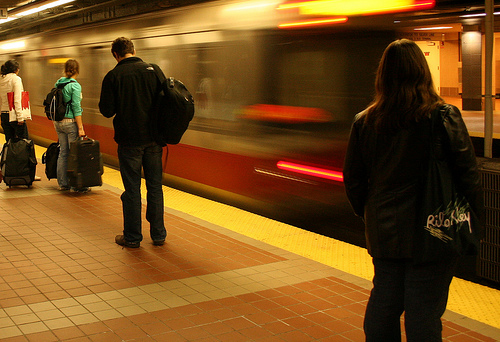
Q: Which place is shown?
A: It is a sidewalk.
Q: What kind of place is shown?
A: It is a sidewalk.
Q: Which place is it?
A: It is a sidewalk.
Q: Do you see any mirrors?
A: No, there are no mirrors.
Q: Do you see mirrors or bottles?
A: No, there are no mirrors or bottles.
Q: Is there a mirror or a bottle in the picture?
A: No, there are no mirrors or bottles.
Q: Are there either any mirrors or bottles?
A: No, there are no mirrors or bottles.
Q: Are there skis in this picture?
A: No, there are no skis.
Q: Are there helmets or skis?
A: No, there are no skis or helmets.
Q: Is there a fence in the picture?
A: No, there are no fences.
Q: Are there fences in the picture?
A: No, there are no fences.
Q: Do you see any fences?
A: No, there are no fences.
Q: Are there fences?
A: No, there are no fences.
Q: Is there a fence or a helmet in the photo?
A: No, there are no fences or helmets.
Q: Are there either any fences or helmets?
A: No, there are no fences or helmets.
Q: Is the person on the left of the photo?
A: Yes, the person is on the left of the image.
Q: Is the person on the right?
A: No, the person is on the left of the image.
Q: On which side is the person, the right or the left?
A: The person is on the left of the image.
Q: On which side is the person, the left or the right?
A: The person is on the left of the image.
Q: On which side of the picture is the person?
A: The person is on the left of the image.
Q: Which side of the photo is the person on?
A: The person is on the left of the image.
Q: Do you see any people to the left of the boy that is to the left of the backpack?
A: Yes, there is a person to the left of the boy.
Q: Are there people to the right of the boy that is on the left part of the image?
A: No, the person is to the left of the boy.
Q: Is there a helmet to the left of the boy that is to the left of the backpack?
A: No, there is a person to the left of the boy.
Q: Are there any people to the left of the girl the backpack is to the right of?
A: Yes, there is a person to the left of the girl.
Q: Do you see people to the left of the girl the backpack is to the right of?
A: Yes, there is a person to the left of the girl.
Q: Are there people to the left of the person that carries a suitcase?
A: Yes, there is a person to the left of the girl.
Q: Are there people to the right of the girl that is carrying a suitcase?
A: No, the person is to the left of the girl.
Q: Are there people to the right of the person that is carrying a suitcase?
A: No, the person is to the left of the girl.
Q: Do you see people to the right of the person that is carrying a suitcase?
A: No, the person is to the left of the girl.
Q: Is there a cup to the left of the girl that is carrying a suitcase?
A: No, there is a person to the left of the girl.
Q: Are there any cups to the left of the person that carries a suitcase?
A: No, there is a person to the left of the girl.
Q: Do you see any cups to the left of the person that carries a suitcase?
A: No, there is a person to the left of the girl.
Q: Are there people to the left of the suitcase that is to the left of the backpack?
A: Yes, there is a person to the left of the suitcase.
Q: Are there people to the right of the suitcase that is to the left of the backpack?
A: No, the person is to the left of the suitcase.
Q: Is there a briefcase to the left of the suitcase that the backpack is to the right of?
A: No, there is a person to the left of the suitcase.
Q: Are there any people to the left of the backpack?
A: Yes, there is a person to the left of the backpack.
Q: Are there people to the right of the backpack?
A: No, the person is to the left of the backpack.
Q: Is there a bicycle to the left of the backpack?
A: No, there is a person to the left of the backpack.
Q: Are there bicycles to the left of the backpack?
A: No, there is a person to the left of the backpack.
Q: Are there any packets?
A: No, there are no packets.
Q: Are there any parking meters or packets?
A: No, there are no packets or parking meters.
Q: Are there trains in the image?
A: Yes, there is a train.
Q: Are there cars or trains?
A: Yes, there is a train.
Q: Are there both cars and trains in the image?
A: No, there is a train but no cars.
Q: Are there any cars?
A: No, there are no cars.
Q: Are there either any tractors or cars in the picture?
A: No, there are no cars or tractors.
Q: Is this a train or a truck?
A: This is a train.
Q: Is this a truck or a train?
A: This is a train.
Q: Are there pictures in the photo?
A: No, there are no pictures.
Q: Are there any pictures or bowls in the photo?
A: No, there are no pictures or bowls.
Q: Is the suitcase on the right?
A: No, the suitcase is on the left of the image.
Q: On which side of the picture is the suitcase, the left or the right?
A: The suitcase is on the left of the image.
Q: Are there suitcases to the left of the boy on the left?
A: Yes, there is a suitcase to the left of the boy.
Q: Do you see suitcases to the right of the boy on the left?
A: No, the suitcase is to the left of the boy.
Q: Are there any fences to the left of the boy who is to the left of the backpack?
A: No, there is a suitcase to the left of the boy.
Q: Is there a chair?
A: No, there are no chairs.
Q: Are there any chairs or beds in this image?
A: No, there are no chairs or beds.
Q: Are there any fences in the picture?
A: No, there are no fences.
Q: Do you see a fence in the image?
A: No, there are no fences.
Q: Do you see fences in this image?
A: No, there are no fences.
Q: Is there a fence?
A: No, there are no fences.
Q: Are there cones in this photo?
A: No, there are no cones.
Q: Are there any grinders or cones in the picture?
A: No, there are no cones or grinders.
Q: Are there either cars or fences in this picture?
A: No, there are no fences or cars.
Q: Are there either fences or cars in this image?
A: No, there are no fences or cars.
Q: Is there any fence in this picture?
A: No, there are no fences.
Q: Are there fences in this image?
A: No, there are no fences.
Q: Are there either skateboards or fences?
A: No, there are no fences or skateboards.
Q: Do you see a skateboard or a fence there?
A: No, there are no fences or skateboards.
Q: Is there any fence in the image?
A: No, there are no fences.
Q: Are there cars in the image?
A: No, there are no cars.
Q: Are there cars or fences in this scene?
A: No, there are no cars or fences.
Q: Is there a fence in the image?
A: No, there are no fences.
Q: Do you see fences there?
A: No, there are no fences.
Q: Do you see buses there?
A: Yes, there is a bus.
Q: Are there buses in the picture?
A: Yes, there is a bus.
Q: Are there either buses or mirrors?
A: Yes, there is a bus.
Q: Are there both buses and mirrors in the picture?
A: No, there is a bus but no mirrors.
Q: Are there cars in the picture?
A: No, there are no cars.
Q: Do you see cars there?
A: No, there are no cars.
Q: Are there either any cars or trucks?
A: No, there are no cars or trucks.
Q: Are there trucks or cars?
A: No, there are no cars or trucks.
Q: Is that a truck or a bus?
A: That is a bus.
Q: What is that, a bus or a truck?
A: That is a bus.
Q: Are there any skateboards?
A: No, there are no skateboards.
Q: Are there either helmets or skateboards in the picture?
A: No, there are no skateboards or helmets.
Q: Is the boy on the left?
A: Yes, the boy is on the left of the image.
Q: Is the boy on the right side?
A: No, the boy is on the left of the image.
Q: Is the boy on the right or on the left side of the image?
A: The boy is on the left of the image.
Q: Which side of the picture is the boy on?
A: The boy is on the left of the image.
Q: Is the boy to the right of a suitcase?
A: Yes, the boy is to the right of a suitcase.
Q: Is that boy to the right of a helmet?
A: No, the boy is to the right of a suitcase.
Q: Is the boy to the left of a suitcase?
A: No, the boy is to the right of a suitcase.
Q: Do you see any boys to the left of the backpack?
A: Yes, there is a boy to the left of the backpack.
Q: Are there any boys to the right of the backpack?
A: No, the boy is to the left of the backpack.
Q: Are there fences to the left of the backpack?
A: No, there is a boy to the left of the backpack.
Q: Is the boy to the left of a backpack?
A: Yes, the boy is to the left of a backpack.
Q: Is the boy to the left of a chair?
A: No, the boy is to the left of a backpack.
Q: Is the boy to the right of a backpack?
A: No, the boy is to the left of a backpack.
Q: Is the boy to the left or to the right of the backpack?
A: The boy is to the left of the backpack.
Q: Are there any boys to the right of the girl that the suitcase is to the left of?
A: Yes, there is a boy to the right of the girl.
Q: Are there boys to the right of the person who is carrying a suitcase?
A: Yes, there is a boy to the right of the girl.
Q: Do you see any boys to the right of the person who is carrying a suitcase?
A: Yes, there is a boy to the right of the girl.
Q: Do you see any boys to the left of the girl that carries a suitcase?
A: No, the boy is to the right of the girl.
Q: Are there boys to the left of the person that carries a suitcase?
A: No, the boy is to the right of the girl.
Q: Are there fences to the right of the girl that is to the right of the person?
A: No, there is a boy to the right of the girl.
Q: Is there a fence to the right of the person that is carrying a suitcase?
A: No, there is a boy to the right of the girl.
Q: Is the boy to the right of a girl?
A: Yes, the boy is to the right of a girl.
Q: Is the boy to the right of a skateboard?
A: No, the boy is to the right of a girl.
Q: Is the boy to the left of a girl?
A: No, the boy is to the right of a girl.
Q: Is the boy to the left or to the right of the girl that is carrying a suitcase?
A: The boy is to the right of the girl.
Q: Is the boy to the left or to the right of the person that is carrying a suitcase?
A: The boy is to the right of the girl.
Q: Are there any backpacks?
A: Yes, there is a backpack.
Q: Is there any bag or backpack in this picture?
A: Yes, there is a backpack.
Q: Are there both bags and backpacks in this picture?
A: Yes, there are both a backpack and a bag.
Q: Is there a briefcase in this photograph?
A: No, there are no briefcases.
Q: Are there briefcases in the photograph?
A: No, there are no briefcases.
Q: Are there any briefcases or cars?
A: No, there are no briefcases or cars.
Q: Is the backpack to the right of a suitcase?
A: Yes, the backpack is to the right of a suitcase.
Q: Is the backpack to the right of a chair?
A: No, the backpack is to the right of a suitcase.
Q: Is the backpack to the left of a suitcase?
A: No, the backpack is to the right of a suitcase.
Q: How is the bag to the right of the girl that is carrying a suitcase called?
A: The bag is a backpack.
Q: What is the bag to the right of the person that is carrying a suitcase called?
A: The bag is a backpack.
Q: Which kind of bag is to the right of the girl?
A: The bag is a backpack.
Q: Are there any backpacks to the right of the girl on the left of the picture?
A: Yes, there is a backpack to the right of the girl.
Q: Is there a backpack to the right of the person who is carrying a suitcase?
A: Yes, there is a backpack to the right of the girl.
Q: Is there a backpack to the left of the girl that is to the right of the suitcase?
A: No, the backpack is to the right of the girl.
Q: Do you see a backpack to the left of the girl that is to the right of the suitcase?
A: No, the backpack is to the right of the girl.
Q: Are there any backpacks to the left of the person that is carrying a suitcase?
A: No, the backpack is to the right of the girl.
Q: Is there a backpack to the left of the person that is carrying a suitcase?
A: No, the backpack is to the right of the girl.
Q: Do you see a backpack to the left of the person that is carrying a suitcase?
A: No, the backpack is to the right of the girl.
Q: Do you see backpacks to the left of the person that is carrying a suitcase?
A: No, the backpack is to the right of the girl.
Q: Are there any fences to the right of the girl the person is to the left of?
A: No, there is a backpack to the right of the girl.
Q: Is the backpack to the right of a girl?
A: Yes, the backpack is to the right of a girl.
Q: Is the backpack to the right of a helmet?
A: No, the backpack is to the right of a girl.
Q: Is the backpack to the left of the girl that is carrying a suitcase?
A: No, the backpack is to the right of the girl.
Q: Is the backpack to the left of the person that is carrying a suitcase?
A: No, the backpack is to the right of the girl.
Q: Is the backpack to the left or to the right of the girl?
A: The backpack is to the right of the girl.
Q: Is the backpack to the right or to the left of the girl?
A: The backpack is to the right of the girl.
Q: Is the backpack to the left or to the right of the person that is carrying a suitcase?
A: The backpack is to the right of the girl.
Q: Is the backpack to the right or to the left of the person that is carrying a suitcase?
A: The backpack is to the right of the girl.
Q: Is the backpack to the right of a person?
A: Yes, the backpack is to the right of a person.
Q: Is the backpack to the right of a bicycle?
A: No, the backpack is to the right of a person.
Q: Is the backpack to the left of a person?
A: No, the backpack is to the right of a person.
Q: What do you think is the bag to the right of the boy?
A: The bag is a backpack.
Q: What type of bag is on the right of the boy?
A: The bag is a backpack.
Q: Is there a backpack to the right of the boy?
A: Yes, there is a backpack to the right of the boy.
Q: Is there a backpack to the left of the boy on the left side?
A: No, the backpack is to the right of the boy.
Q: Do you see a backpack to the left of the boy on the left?
A: No, the backpack is to the right of the boy.